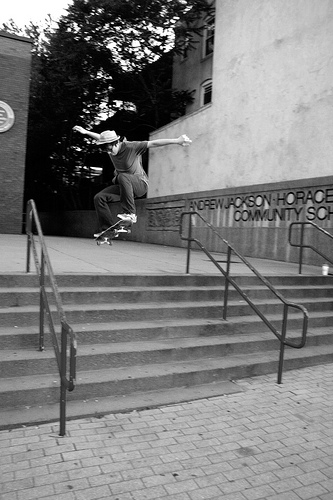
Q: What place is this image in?
A: It is at the sidewalk.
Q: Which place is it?
A: It is a sidewalk.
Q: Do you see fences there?
A: No, there are no fences.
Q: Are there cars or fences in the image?
A: No, there are no fences or cars.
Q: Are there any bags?
A: No, there are no bags.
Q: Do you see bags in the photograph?
A: No, there are no bags.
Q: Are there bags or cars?
A: No, there are no bags or cars.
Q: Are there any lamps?
A: No, there are no lamps.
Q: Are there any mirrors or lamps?
A: No, there are no lamps or mirrors.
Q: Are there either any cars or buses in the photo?
A: No, there are no cars or buses.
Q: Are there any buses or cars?
A: No, there are no cars or buses.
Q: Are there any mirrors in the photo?
A: No, there are no mirrors.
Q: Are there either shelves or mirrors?
A: No, there are no mirrors or shelves.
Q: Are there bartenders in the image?
A: No, there are no bartenders.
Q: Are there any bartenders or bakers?
A: No, there are no bartenders or bakers.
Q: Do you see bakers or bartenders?
A: No, there are no bartenders or bakers.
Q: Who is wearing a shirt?
A: The boy is wearing a shirt.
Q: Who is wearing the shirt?
A: The boy is wearing a shirt.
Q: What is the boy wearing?
A: The boy is wearing a shirt.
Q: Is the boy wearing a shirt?
A: Yes, the boy is wearing a shirt.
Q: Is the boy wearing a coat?
A: No, the boy is wearing a shirt.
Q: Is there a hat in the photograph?
A: Yes, there is a hat.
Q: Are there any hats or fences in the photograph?
A: Yes, there is a hat.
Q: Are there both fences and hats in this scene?
A: No, there is a hat but no fences.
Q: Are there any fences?
A: No, there are no fences.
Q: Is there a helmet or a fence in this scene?
A: No, there are no fences or helmets.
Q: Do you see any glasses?
A: No, there are no glasses.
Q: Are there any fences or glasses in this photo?
A: No, there are no glasses or fences.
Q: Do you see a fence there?
A: No, there are no fences.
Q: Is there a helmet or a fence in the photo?
A: No, there are no fences or helmets.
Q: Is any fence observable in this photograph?
A: No, there are no fences.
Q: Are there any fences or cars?
A: No, there are no fences or cars.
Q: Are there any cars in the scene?
A: No, there are no cars.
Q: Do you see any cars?
A: No, there are no cars.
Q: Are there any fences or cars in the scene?
A: No, there are no cars or fences.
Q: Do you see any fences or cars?
A: No, there are no cars or fences.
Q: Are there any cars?
A: No, there are no cars.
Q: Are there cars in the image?
A: No, there are no cars.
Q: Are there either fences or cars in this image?
A: No, there are no cars or fences.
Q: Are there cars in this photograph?
A: No, there are no cars.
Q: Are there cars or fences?
A: No, there are no cars or fences.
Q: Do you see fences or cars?
A: No, there are no cars or fences.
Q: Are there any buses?
A: No, there are no buses.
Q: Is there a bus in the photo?
A: No, there are no buses.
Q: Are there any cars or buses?
A: No, there are no buses or cars.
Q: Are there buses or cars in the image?
A: No, there are no buses or cars.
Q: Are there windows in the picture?
A: Yes, there is a window.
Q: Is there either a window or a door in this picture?
A: Yes, there is a window.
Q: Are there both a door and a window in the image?
A: No, there is a window but no doors.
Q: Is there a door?
A: No, there are no doors.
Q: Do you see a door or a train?
A: No, there are no doors or trains.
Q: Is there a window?
A: Yes, there is a window.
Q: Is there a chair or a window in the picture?
A: Yes, there is a window.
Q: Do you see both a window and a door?
A: No, there is a window but no doors.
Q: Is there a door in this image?
A: No, there are no doors.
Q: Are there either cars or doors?
A: No, there are no doors or cars.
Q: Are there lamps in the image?
A: No, there are no lamps.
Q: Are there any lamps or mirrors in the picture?
A: No, there are no lamps or mirrors.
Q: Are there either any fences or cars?
A: No, there are no cars or fences.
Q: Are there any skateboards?
A: Yes, there is a skateboard.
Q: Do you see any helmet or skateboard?
A: Yes, there is a skateboard.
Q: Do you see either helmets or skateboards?
A: Yes, there is a skateboard.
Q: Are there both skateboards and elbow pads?
A: No, there is a skateboard but no elbow pads.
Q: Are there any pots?
A: No, there are no pots.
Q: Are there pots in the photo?
A: No, there are no pots.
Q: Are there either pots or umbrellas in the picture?
A: No, there are no pots or umbrellas.